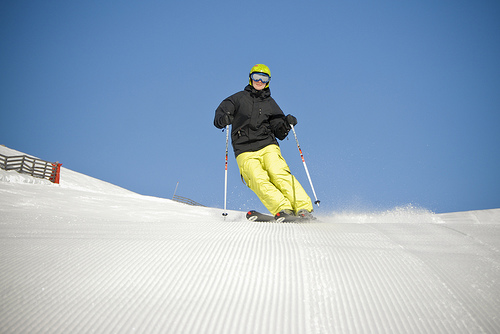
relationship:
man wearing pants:
[217, 87, 327, 221] [256, 168, 286, 196]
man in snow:
[217, 87, 327, 221] [127, 215, 220, 284]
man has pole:
[217, 87, 327, 221] [295, 142, 312, 164]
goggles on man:
[249, 71, 278, 88] [217, 87, 327, 221]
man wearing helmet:
[217, 87, 327, 221] [251, 62, 278, 72]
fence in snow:
[37, 156, 65, 175] [127, 215, 220, 284]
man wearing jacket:
[217, 87, 327, 221] [242, 95, 274, 128]